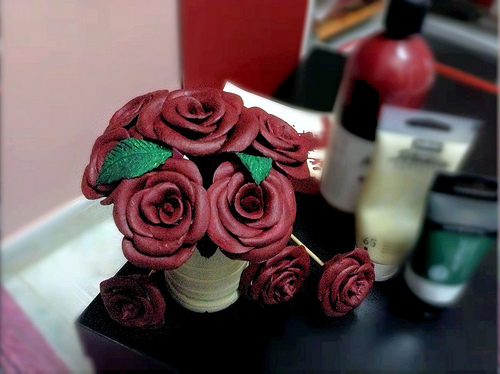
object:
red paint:
[321, 1, 438, 218]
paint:
[400, 169, 500, 310]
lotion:
[353, 101, 485, 282]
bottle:
[317, 0, 437, 216]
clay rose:
[205, 157, 299, 264]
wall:
[0, 0, 190, 245]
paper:
[222, 79, 338, 183]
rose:
[315, 246, 378, 316]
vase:
[162, 247, 249, 317]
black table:
[78, 43, 500, 374]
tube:
[401, 170, 496, 309]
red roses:
[109, 157, 212, 272]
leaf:
[92, 136, 174, 186]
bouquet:
[237, 244, 313, 306]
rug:
[0, 193, 138, 374]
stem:
[289, 233, 324, 267]